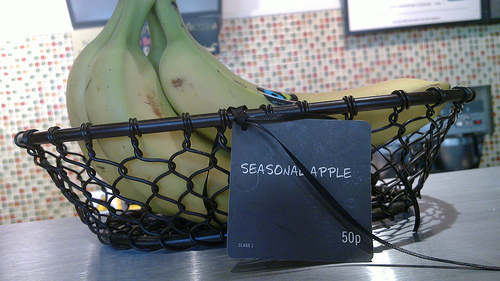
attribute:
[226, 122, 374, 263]
card — black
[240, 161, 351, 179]
writing — white, bold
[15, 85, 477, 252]
basket — black, metallic, wrong, metal, for fruit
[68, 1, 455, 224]
bananas — yellow, a bunch, ripe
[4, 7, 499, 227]
wall — tile, tiled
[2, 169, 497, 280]
table — grey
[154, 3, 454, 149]
banana — yellow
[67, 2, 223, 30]
screen — black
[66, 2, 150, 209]
banana — yellow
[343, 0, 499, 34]
painting — obstructed